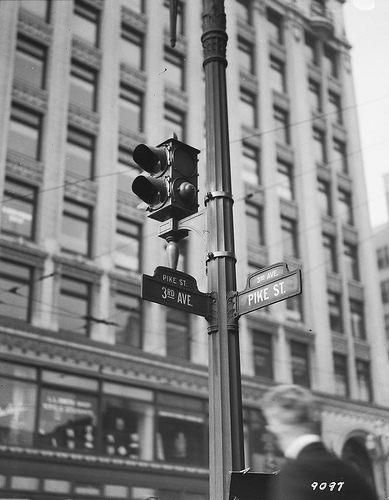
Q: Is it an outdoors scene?
A: Yes, it is outdoors.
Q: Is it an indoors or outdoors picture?
A: It is outdoors.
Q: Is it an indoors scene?
A: No, it is outdoors.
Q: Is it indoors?
A: No, it is outdoors.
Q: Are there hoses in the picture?
A: No, there are no hoses.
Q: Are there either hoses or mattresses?
A: No, there are no hoses or mattresses.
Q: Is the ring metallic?
A: Yes, the ring is metallic.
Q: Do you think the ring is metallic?
A: Yes, the ring is metallic.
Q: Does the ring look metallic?
A: Yes, the ring is metallic.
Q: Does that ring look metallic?
A: Yes, the ring is metallic.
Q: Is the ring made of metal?
A: Yes, the ring is made of metal.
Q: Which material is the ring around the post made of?
A: The ring is made of metal.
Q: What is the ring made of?
A: The ring is made of metal.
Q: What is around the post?
A: The ring is around the post.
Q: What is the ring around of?
A: The ring is around the post.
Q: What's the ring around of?
A: The ring is around the post.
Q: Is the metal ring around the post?
A: Yes, the ring is around the post.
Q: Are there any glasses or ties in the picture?
A: No, there are no glasses or ties.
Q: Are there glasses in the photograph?
A: No, there are no glasses.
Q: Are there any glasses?
A: No, there are no glasses.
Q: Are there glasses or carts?
A: No, there are no glasses or carts.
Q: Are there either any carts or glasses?
A: No, there are no glasses or carts.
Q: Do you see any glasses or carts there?
A: No, there are no glasses or carts.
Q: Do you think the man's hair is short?
A: Yes, the hair is short.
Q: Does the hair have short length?
A: Yes, the hair is short.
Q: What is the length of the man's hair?
A: The hair is short.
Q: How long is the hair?
A: The hair is short.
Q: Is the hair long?
A: No, the hair is short.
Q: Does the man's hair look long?
A: No, the hair is short.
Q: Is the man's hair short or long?
A: The hair is short.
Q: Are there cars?
A: No, there are no cars.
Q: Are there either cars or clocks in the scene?
A: No, there are no cars or clocks.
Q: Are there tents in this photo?
A: No, there are no tents.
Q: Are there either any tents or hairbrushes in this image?
A: No, there are no tents or hairbrushes.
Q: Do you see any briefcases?
A: Yes, there is a briefcase.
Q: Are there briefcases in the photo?
A: Yes, there is a briefcase.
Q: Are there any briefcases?
A: Yes, there is a briefcase.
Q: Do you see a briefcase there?
A: Yes, there is a briefcase.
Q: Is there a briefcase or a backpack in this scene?
A: Yes, there is a briefcase.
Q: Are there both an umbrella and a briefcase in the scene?
A: No, there is a briefcase but no umbrellas.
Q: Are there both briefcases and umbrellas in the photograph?
A: No, there is a briefcase but no umbrellas.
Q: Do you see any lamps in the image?
A: No, there are no lamps.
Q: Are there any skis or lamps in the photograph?
A: No, there are no lamps or skis.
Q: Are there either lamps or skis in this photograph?
A: No, there are no lamps or skis.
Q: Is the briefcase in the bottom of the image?
A: Yes, the briefcase is in the bottom of the image.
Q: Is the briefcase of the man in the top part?
A: No, the briefcase is in the bottom of the image.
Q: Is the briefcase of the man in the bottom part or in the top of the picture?
A: The briefcase is in the bottom of the image.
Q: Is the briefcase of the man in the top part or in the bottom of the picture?
A: The briefcase is in the bottom of the image.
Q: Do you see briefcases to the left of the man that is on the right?
A: Yes, there is a briefcase to the left of the man.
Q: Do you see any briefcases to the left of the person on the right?
A: Yes, there is a briefcase to the left of the man.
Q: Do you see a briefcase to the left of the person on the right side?
A: Yes, there is a briefcase to the left of the man.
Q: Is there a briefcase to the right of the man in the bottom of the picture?
A: No, the briefcase is to the left of the man.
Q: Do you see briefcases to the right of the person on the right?
A: No, the briefcase is to the left of the man.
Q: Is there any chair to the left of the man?
A: No, there is a briefcase to the left of the man.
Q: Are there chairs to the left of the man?
A: No, there is a briefcase to the left of the man.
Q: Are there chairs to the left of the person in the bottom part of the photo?
A: No, there is a briefcase to the left of the man.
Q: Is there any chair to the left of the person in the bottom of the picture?
A: No, there is a briefcase to the left of the man.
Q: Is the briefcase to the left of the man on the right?
A: Yes, the briefcase is to the left of the man.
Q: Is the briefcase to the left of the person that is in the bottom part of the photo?
A: Yes, the briefcase is to the left of the man.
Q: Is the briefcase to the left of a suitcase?
A: No, the briefcase is to the left of the man.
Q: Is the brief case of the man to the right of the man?
A: No, the briefcase is to the left of the man.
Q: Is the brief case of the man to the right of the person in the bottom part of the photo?
A: No, the briefcase is to the left of the man.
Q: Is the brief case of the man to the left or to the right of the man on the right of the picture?
A: The briefcase is to the left of the man.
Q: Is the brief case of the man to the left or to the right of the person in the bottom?
A: The briefcase is to the left of the man.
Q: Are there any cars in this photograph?
A: No, there are no cars.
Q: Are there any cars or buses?
A: No, there are no cars or buses.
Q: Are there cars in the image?
A: No, there are no cars.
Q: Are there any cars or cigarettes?
A: No, there are no cars or cigarettes.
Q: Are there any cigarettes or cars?
A: No, there are no cars or cigarettes.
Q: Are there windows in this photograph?
A: Yes, there is a window.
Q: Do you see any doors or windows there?
A: Yes, there is a window.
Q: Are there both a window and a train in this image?
A: No, there is a window but no trains.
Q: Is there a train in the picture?
A: No, there are no trains.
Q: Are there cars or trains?
A: No, there are no trains or cars.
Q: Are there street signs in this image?
A: Yes, there is a street sign.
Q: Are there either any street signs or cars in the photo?
A: Yes, there is a street sign.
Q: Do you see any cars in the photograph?
A: No, there are no cars.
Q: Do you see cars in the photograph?
A: No, there are no cars.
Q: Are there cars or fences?
A: No, there are no cars or fences.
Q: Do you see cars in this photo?
A: No, there are no cars.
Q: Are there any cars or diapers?
A: No, there are no cars or diapers.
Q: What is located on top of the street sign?
A: The lamp post is on top of the street sign.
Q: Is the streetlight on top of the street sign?
A: Yes, the streetlight is on top of the street sign.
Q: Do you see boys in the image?
A: No, there are no boys.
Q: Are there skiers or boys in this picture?
A: No, there are no boys or skiers.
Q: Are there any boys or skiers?
A: No, there are no boys or skiers.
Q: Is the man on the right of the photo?
A: Yes, the man is on the right of the image.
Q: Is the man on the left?
A: No, the man is on the right of the image.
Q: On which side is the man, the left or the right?
A: The man is on the right of the image.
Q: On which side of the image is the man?
A: The man is on the right of the image.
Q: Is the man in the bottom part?
A: Yes, the man is in the bottom of the image.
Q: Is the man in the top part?
A: No, the man is in the bottom of the image.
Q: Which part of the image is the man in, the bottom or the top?
A: The man is in the bottom of the image.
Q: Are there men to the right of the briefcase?
A: Yes, there is a man to the right of the briefcase.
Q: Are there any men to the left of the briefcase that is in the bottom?
A: No, the man is to the right of the brief case.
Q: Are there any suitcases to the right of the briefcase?
A: No, there is a man to the right of the briefcase.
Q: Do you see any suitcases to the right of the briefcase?
A: No, there is a man to the right of the briefcase.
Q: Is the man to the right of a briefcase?
A: Yes, the man is to the right of a briefcase.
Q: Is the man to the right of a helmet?
A: No, the man is to the right of a briefcase.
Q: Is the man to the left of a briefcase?
A: No, the man is to the right of a briefcase.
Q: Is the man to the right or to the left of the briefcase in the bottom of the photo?
A: The man is to the right of the brief case.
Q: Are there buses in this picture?
A: No, there are no buses.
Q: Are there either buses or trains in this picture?
A: No, there are no buses or trains.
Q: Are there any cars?
A: No, there are no cars.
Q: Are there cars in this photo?
A: No, there are no cars.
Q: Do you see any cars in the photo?
A: No, there are no cars.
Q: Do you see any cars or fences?
A: No, there are no cars or fences.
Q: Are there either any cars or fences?
A: No, there are no cars or fences.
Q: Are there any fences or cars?
A: No, there are no cars or fences.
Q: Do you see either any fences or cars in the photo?
A: No, there are no cars or fences.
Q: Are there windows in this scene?
A: Yes, there is a window.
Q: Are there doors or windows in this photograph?
A: Yes, there is a window.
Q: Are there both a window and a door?
A: No, there is a window but no doors.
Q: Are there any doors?
A: No, there are no doors.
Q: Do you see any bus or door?
A: No, there are no doors or buses.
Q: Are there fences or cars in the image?
A: No, there are no cars or fences.